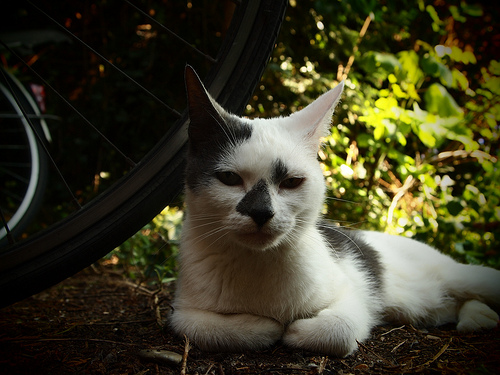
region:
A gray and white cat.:
[170, 62, 497, 348]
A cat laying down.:
[165, 62, 495, 347]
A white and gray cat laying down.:
[173, 62, 498, 357]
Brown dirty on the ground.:
[1, 263, 498, 373]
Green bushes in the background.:
[245, 0, 499, 268]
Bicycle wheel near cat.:
[1, 0, 278, 299]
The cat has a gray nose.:
[248, 209, 273, 223]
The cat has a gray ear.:
[184, 63, 229, 140]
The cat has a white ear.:
[296, 82, 344, 146]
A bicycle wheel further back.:
[1, 72, 51, 249]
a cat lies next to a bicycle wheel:
[171, 60, 494, 358]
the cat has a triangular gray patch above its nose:
[236, 174, 277, 228]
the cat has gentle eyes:
[207, 165, 311, 195]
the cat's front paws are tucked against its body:
[166, 300, 381, 360]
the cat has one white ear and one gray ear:
[176, 62, 358, 174]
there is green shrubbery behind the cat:
[244, 1, 499, 272]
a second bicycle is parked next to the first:
[3, 2, 61, 258]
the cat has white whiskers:
[177, 210, 374, 260]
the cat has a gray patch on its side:
[316, 219, 392, 312]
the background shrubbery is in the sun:
[281, 43, 497, 235]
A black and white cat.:
[168, 62, 498, 354]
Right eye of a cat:
[213, 169, 243, 189]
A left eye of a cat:
[278, 174, 305, 191]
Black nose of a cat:
[248, 207, 273, 223]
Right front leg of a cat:
[169, 305, 280, 350]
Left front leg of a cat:
[284, 304, 371, 359]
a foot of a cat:
[458, 300, 498, 330]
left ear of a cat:
[292, 87, 344, 155]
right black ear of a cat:
[187, 88, 237, 149]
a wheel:
[1, 88, 256, 304]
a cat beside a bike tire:
[19, 18, 493, 373]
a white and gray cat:
[171, 61, 499, 354]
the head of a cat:
[179, 60, 344, 253]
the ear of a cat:
[296, 76, 346, 140]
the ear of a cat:
[173, 64, 221, 123]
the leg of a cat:
[178, 302, 283, 350]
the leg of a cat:
[283, 312, 368, 352]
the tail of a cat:
[436, 250, 499, 295]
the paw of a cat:
[462, 304, 498, 331]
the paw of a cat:
[283, 317, 310, 350]